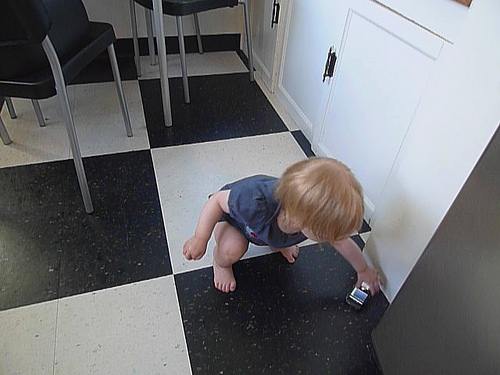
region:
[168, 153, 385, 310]
Toddler is blonde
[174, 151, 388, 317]
Child is squatting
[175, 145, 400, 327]
Child wears blue cloths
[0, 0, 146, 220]
Chair is black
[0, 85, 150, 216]
Legs of chair are silver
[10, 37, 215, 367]
Floor is checkered white and black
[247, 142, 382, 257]
Hair of child is short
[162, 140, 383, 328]
Child is barefoot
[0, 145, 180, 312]
Black tile of floor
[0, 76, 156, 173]
White tile of floor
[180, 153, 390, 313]
a toddler bent over picking up an object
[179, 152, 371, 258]
a toddler wearing a blue shirt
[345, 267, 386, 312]
hand grasping object between thumb and forefinger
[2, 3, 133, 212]
black chair with metal legs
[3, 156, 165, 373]
black and white tile floor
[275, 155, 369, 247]
blond hair on toddler's head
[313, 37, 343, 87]
dark hinge on white cabinet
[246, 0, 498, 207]
white cabinets with white doors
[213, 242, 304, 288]
toddler's bare feet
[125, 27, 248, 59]
black baseboard on bottom of wall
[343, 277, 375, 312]
cellphone on floor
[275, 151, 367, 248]
blonde hair covers ears of child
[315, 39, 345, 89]
black metal handle of white kitchen cabinet door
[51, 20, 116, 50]
black chair seat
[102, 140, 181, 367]
black and white checkered floor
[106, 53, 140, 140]
silver colored metal chair leg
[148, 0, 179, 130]
silver colored metal table leg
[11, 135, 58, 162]
shadow of chair leg cast on floor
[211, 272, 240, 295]
5 toes of child's foot on black checkered tile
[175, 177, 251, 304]
right arm and right leg of toddler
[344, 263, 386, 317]
A small plastic container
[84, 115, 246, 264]
A black and white tiled floor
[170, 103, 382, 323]
Small child with blonde hair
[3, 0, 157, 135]
A black and silver chair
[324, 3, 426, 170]
A cabinet door with a black handle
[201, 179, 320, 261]
A blue shirt on the small child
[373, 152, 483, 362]
A silver appliance in the kitchen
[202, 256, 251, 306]
A foot with 5 little toes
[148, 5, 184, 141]
A silver leg to the table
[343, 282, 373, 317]
A blue and white lable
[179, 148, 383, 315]
blonde hair boy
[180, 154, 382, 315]
blonde hair boy on a black and white floor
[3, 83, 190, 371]
black and white checkered floor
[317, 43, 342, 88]
black handle of the cabinet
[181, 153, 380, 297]
blonde hair boy wearing a blue shirt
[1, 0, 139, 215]
black chair on a black and white checkered floor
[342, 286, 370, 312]
black object on the floor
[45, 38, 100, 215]
metal leg of the chair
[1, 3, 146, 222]
black and silver chair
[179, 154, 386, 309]
baby boy playing with an object